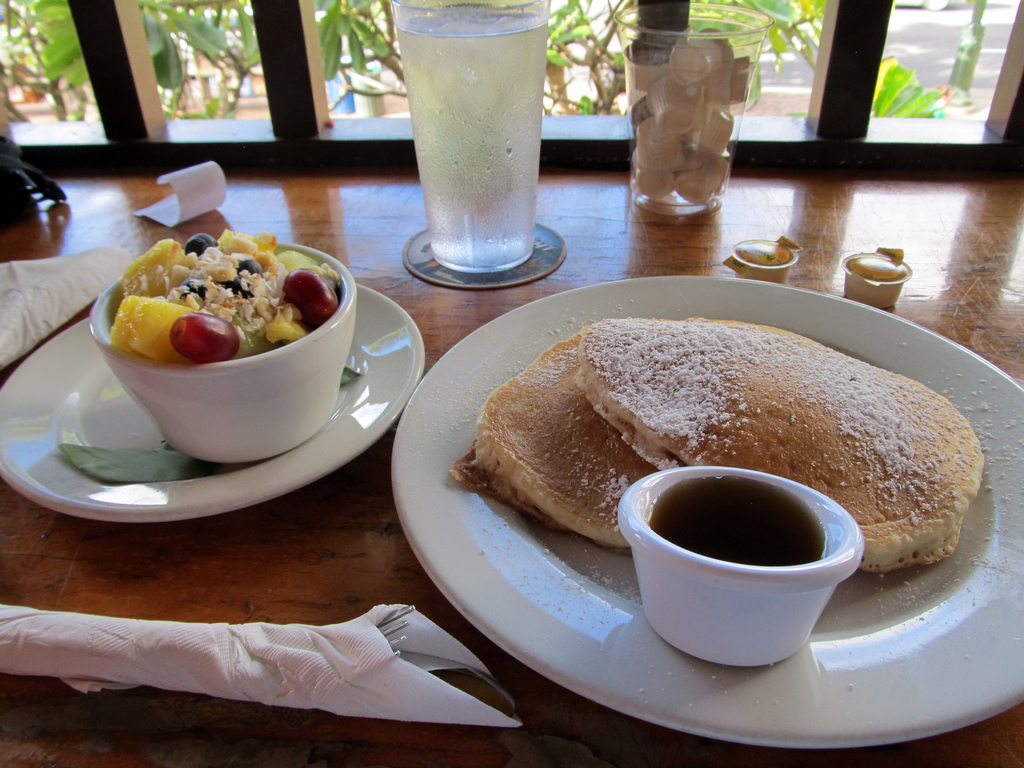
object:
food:
[106, 294, 193, 364]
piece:
[235, 258, 264, 278]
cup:
[614, 0, 777, 217]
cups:
[388, 0, 556, 276]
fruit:
[281, 268, 342, 326]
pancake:
[447, 316, 667, 554]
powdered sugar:
[582, 313, 752, 470]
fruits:
[183, 232, 219, 255]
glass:
[391, 0, 554, 275]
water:
[394, 24, 549, 268]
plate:
[391, 273, 1024, 756]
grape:
[168, 313, 242, 365]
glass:
[620, 1, 780, 219]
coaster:
[401, 219, 567, 291]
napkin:
[0, 602, 528, 735]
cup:
[88, 232, 365, 466]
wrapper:
[130, 159, 228, 228]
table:
[9, 159, 1024, 759]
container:
[615, 465, 866, 670]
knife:
[0, 644, 528, 736]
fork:
[0, 601, 422, 688]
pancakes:
[572, 313, 989, 578]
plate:
[0, 277, 427, 525]